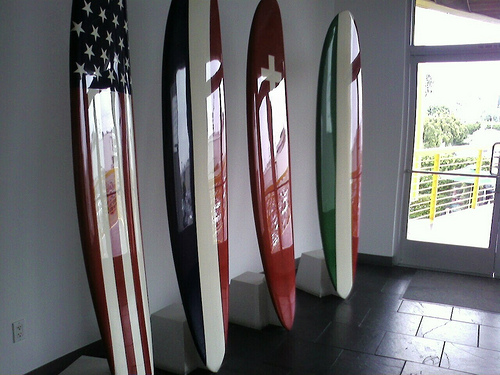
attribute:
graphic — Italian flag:
[320, 17, 358, 295]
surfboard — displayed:
[242, 0, 304, 332]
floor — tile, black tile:
[110, 239, 499, 374]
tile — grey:
[351, 287, 403, 314]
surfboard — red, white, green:
[314, 15, 372, 303]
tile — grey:
[416, 315, 478, 347]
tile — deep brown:
[365, 279, 472, 374]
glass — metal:
[392, 29, 499, 237]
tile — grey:
[316, 322, 387, 354]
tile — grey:
[374, 326, 446, 366]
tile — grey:
[437, 339, 499, 374]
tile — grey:
[358, 307, 422, 333]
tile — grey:
[356, 301, 418, 336]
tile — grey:
[415, 311, 480, 346]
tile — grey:
[268, 335, 342, 370]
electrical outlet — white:
[11, 316, 26, 343]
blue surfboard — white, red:
[165, 15, 255, 214]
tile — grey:
[361, 273, 412, 299]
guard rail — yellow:
[406, 142, 498, 222]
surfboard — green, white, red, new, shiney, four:
[313, 5, 360, 300]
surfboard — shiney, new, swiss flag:
[247, 0, 295, 331]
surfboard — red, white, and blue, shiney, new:
[160, 0, 230, 373]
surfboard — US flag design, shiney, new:
[70, 1, 153, 373]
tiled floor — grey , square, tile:
[223, 262, 498, 374]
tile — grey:
[473, 307, 498, 349]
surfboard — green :
[309, 9, 371, 308]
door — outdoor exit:
[387, 52, 499, 285]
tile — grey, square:
[412, 313, 480, 350]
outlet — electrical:
[6, 313, 31, 340]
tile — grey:
[447, 306, 498, 347]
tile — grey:
[377, 288, 495, 367]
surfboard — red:
[246, 14, 313, 333]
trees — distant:
[421, 93, 491, 143]